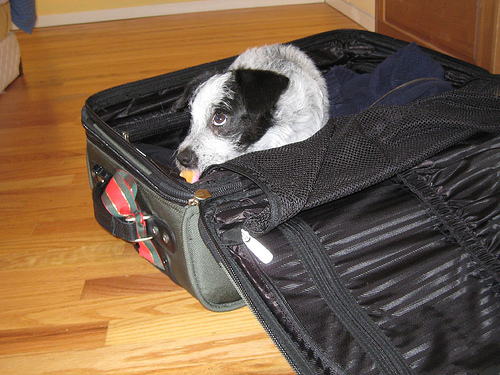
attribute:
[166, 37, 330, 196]
dog — black, white, furry, small, sad, cute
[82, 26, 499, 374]
luggage — open, large, black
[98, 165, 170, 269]
ribbon — red, green, red green, gold, grey, black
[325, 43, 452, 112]
clothes — navy blue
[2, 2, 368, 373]
floor — hardwood, wooden, wood, brown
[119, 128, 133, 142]
zipper — silver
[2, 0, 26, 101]
mattress — tan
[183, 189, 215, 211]
zipper — gold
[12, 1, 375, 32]
trim — white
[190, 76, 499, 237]
divider — mesh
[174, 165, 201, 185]
toy — yellow, pink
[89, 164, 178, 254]
handle — black